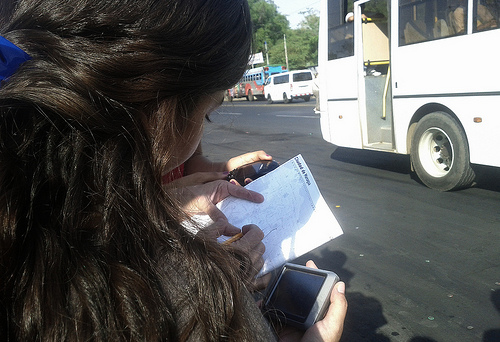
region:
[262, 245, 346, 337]
silver gps in woman's right hand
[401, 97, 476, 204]
black tire on white wheel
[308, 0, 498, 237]
large white passenger bus on street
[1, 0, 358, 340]
dark brown long hair pulled back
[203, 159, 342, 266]
paper being written on with pencil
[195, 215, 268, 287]
yellow pencil in right hand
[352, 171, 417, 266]
black smooth paved street with litter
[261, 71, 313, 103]
white van with dark windows on street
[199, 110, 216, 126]
curled eyelashes on woman's face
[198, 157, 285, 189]
black cellular phone in left hand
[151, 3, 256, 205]
girl with dark brown hair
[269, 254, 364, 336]
hand holding silver gps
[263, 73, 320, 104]
distant view of white van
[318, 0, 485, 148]
side view of bus with open door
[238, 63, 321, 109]
white van following bus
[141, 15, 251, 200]
side view of young girl's face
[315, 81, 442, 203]
bottom view of bus with shadow on pavement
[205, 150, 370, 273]
hands holding pencil and map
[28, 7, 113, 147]
light brown highlights in hair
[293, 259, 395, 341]
hand holding device with shadow on pavement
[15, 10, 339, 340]
woman with phone in her hand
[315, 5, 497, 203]
white bus on the street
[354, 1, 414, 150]
open door of the bus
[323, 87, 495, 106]
black stripe on side of bus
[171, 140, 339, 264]
hands holding white piece of paper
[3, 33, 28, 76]
blue hair tie in woman's hair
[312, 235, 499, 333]
shadows on the street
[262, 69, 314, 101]
white van parked on street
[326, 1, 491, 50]
windows of white bus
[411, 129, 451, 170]
white tire rim of tire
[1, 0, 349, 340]
Woman looking at a map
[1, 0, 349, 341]
Woman holding a GPS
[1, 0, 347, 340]
Woman with long brunette hair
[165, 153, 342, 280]
White paper map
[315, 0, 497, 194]
White travel bus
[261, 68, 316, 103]
White commercial van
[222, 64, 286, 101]
Blue and red school bus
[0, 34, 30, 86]
Silk blue hair bow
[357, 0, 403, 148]
Open bus door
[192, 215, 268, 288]
Hand writing with a pencil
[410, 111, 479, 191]
A wheel on a white bus.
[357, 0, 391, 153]
A door on a white bus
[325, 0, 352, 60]
A window on a white bus.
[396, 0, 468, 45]
A window on a white bus.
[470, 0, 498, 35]
A window on a white bus.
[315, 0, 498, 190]
A white bus.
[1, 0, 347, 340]
A woman holding an electronic device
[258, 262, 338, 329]
A small electronic device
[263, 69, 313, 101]
A white van in traffic.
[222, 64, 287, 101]
A multicolored bus in traffic.